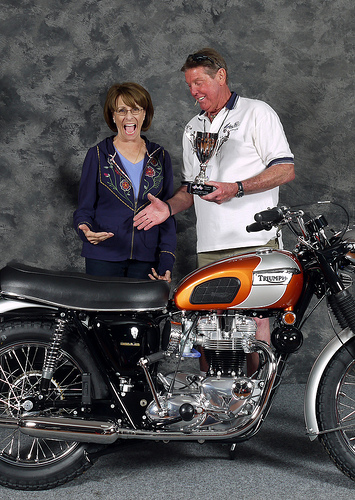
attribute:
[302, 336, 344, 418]
fender — silver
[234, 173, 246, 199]
watch — black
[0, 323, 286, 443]
pipe — chrome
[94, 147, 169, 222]
embroidery — purple, floral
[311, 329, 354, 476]
tire — from motorcycle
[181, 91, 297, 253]
shirt — white, blue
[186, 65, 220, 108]
face — surprised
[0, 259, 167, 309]
leather seat — black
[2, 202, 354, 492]
motorcycle — black, orange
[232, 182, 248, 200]
wrist watch — black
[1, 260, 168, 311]
seat — black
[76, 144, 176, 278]
jacket — decorated, blue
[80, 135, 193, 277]
jacket — navy blue